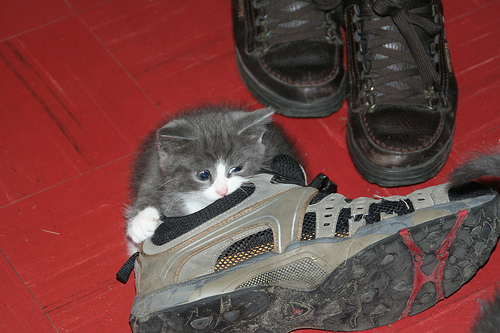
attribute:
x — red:
[391, 211, 468, 322]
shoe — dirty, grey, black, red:
[132, 176, 497, 330]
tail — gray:
[444, 148, 499, 180]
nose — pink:
[214, 185, 228, 196]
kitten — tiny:
[193, 166, 210, 184]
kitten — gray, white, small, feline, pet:
[125, 102, 309, 246]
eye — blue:
[192, 158, 215, 187]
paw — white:
[129, 207, 159, 242]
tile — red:
[2, 1, 499, 332]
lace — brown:
[355, 6, 446, 117]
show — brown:
[230, 1, 357, 123]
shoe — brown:
[336, 5, 463, 187]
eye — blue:
[225, 159, 250, 179]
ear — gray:
[157, 120, 203, 154]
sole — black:
[234, 41, 347, 116]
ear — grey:
[227, 110, 280, 141]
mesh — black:
[217, 224, 275, 274]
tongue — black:
[271, 155, 307, 185]